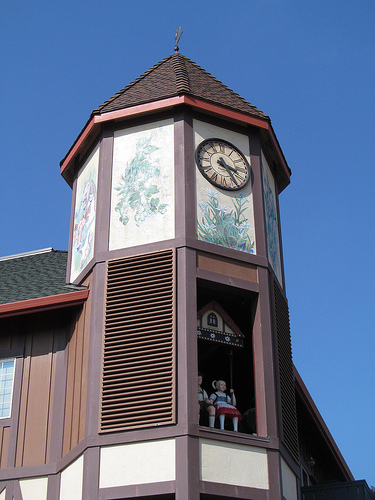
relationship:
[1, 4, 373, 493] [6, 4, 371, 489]
view of sky